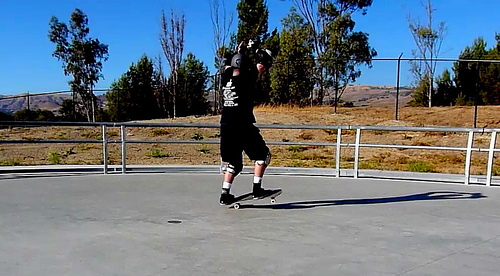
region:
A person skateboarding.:
[215, 40, 286, 212]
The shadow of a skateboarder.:
[227, 189, 484, 210]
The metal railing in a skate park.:
[1, 115, 498, 187]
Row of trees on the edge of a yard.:
[50, 0, 382, 115]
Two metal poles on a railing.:
[98, 120, 128, 175]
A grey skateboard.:
[225, 186, 284, 205]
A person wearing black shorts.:
[217, 35, 287, 207]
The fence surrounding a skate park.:
[2, 50, 496, 132]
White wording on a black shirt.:
[217, 74, 245, 113]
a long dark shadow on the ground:
[233, 187, 488, 214]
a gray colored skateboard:
[226, 188, 281, 209]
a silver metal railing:
[1, 118, 498, 186]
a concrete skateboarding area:
[0, 160, 496, 273]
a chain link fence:
[1, 50, 498, 127]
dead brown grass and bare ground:
[1, 105, 499, 166]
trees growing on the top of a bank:
[0, 0, 498, 127]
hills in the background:
[0, 80, 435, 125]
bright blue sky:
[3, 1, 496, 93]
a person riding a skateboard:
[214, 38, 281, 210]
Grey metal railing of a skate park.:
[1, 117, 498, 192]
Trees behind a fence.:
[2, 0, 499, 121]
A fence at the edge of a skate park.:
[2, 51, 498, 128]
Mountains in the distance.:
[2, 89, 78, 117]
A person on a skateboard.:
[216, 30, 289, 211]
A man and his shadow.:
[214, 30, 488, 210]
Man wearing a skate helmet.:
[218, 37, 290, 208]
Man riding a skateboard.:
[215, 34, 286, 211]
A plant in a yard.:
[142, 143, 173, 163]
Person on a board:
[217, 180, 284, 212]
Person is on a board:
[217, 185, 285, 214]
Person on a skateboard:
[216, 181, 286, 213]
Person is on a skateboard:
[214, 185, 286, 212]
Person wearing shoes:
[217, 184, 267, 206]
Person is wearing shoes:
[219, 184, 266, 204]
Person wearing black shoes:
[216, 183, 268, 207]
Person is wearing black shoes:
[210, 184, 272, 210]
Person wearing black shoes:
[214, 120, 275, 167]